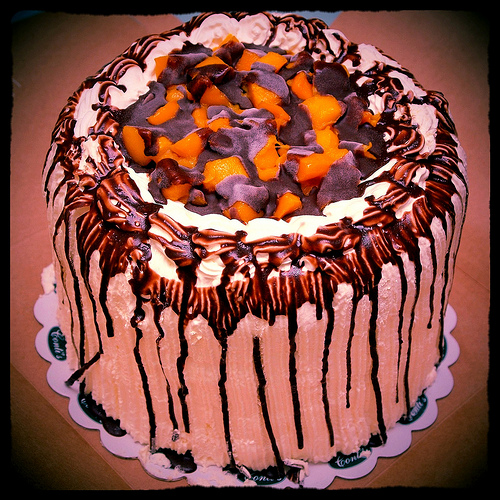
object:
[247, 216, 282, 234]
icing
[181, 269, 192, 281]
sauce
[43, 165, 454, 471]
side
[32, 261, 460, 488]
base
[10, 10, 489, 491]
table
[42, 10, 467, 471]
cake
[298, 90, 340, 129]
slices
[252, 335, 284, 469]
lines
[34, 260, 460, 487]
paper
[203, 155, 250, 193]
fruit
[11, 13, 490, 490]
countertop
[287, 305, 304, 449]
drizzle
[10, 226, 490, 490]
cardboard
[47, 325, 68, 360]
circle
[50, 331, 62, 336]
letter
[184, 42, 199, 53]
syrup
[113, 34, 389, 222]
top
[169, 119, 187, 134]
chocolate